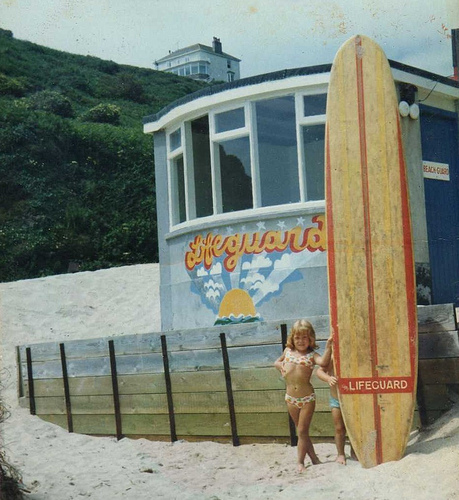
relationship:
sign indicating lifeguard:
[163, 214, 329, 374] [184, 214, 327, 270]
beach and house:
[0, 399, 457, 499] [139, 60, 457, 329]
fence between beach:
[17, 313, 349, 449] [0, 399, 457, 499]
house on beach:
[139, 60, 457, 329] [0, 399, 457, 499]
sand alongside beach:
[2, 411, 457, 499] [0, 399, 457, 499]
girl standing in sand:
[275, 320, 333, 469] [2, 411, 457, 499]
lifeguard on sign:
[184, 214, 327, 270] [163, 214, 329, 374]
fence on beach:
[17, 313, 349, 449] [0, 399, 457, 499]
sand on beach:
[2, 411, 457, 499] [0, 399, 457, 499]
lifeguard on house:
[184, 214, 327, 270] [139, 60, 457, 329]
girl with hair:
[275, 320, 333, 469] [287, 321, 316, 355]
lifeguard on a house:
[184, 214, 327, 270] [139, 60, 457, 329]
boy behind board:
[313, 334, 357, 464] [324, 36, 419, 474]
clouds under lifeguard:
[198, 251, 325, 302] [184, 214, 327, 270]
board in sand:
[324, 36, 419, 474] [2, 411, 457, 499]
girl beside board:
[275, 320, 333, 469] [324, 36, 419, 474]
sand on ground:
[2, 411, 457, 499] [1, 261, 459, 499]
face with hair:
[296, 334, 309, 350] [287, 321, 316, 355]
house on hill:
[154, 36, 241, 87] [0, 32, 206, 95]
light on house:
[399, 98, 410, 116] [139, 60, 457, 329]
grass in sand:
[137, 463, 154, 479] [2, 411, 457, 499]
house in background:
[154, 36, 241, 87] [2, 0, 455, 195]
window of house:
[214, 138, 256, 212] [139, 60, 457, 329]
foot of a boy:
[335, 450, 349, 465] [313, 334, 357, 464]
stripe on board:
[317, 137, 352, 396] [324, 32, 420, 475]